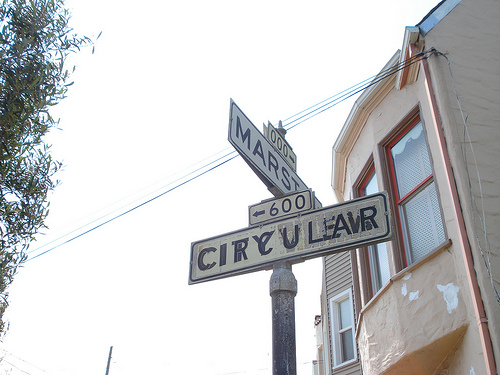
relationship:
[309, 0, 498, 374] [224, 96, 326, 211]
building by sign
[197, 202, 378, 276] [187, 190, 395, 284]
black letters on sign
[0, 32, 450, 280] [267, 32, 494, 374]
wire from house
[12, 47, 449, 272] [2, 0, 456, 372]
telephone wires against cloudless sky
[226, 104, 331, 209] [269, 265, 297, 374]
signs on pole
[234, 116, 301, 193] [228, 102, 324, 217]
letters on sign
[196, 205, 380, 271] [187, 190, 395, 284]
letters on sign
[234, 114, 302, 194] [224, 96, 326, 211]
name on sign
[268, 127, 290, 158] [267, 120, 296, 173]
number on sign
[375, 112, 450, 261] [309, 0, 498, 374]
window on building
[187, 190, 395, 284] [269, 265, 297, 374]
sign on pole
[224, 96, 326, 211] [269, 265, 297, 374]
sign on pole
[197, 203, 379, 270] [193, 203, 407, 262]
name on sign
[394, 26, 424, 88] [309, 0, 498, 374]
gutter on building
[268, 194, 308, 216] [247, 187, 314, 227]
number on sign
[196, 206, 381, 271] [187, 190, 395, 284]
writing on sign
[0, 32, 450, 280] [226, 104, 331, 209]
wire above signs